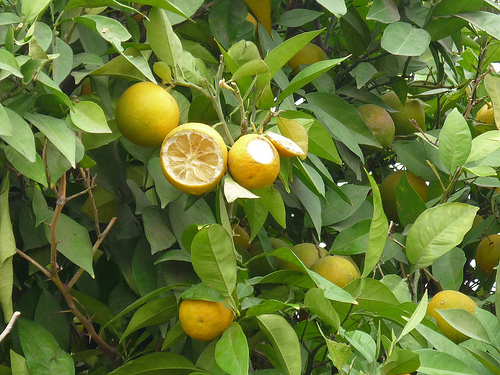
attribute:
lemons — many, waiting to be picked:
[108, 67, 498, 357]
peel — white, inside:
[262, 129, 307, 157]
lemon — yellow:
[176, 299, 224, 339]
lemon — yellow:
[113, 86, 169, 140]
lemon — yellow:
[236, 134, 280, 185]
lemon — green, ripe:
[119, 87, 176, 148]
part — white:
[245, 135, 279, 169]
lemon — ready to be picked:
[178, 299, 233, 339]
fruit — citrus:
[111, 74, 183, 147]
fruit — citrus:
[225, 130, 284, 187]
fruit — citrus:
[176, 285, 237, 340]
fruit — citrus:
[310, 254, 362, 290]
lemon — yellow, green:
[114, 81, 181, 147]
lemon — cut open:
[159, 119, 221, 195]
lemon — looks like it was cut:
[160, 122, 230, 193]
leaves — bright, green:
[31, 112, 78, 168]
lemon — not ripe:
[112, 81, 187, 150]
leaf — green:
[68, 99, 111, 133]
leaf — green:
[22, 110, 75, 168]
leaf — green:
[1, 106, 36, 163]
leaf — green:
[41, 206, 96, 279]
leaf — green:
[31, 69, 73, 112]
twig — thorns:
[51, 267, 96, 334]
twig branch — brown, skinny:
[41, 213, 121, 285]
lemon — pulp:
[160, 119, 225, 198]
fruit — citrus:
[158, 123, 228, 195]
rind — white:
[251, 137, 278, 166]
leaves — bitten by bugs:
[0, 20, 123, 190]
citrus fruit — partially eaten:
[159, 123, 228, 195]